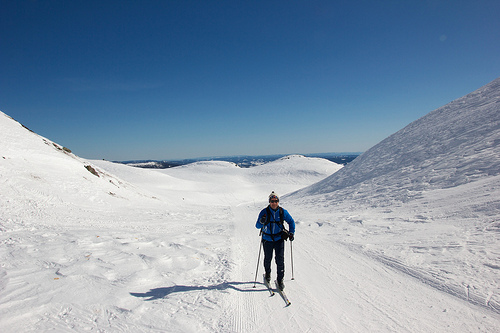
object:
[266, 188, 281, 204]
cap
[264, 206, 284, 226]
chest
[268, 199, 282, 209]
face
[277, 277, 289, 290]
foot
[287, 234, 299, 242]
hand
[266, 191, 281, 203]
head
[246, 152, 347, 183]
hill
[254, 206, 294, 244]
jacket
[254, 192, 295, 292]
man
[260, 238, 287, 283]
pants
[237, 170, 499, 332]
pathway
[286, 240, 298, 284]
pole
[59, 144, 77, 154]
rocks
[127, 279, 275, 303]
shadow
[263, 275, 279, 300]
ski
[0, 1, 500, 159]
sky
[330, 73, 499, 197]
slope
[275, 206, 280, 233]
strap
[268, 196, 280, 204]
sunglasses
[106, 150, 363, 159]
water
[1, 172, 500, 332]
snow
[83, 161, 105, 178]
rock